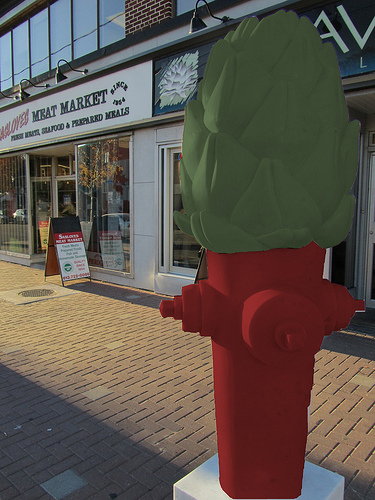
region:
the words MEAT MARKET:
[26, 91, 104, 126]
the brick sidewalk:
[51, 294, 210, 417]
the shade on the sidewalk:
[35, 419, 101, 475]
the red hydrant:
[166, 254, 354, 483]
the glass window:
[76, 151, 137, 268]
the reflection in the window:
[98, 225, 125, 270]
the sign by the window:
[40, 210, 89, 289]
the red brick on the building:
[124, 8, 162, 24]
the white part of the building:
[137, 188, 149, 227]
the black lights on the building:
[4, 54, 91, 106]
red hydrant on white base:
[174, 250, 357, 498]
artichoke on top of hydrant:
[173, 31, 365, 266]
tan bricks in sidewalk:
[59, 322, 146, 383]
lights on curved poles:
[16, 55, 91, 101]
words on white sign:
[62, 241, 87, 277]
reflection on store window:
[79, 138, 130, 245]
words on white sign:
[29, 75, 134, 139]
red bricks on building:
[124, 2, 172, 29]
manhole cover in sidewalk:
[17, 283, 65, 307]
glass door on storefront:
[48, 164, 82, 215]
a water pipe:
[209, 280, 295, 496]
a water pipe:
[235, 346, 289, 487]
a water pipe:
[230, 390, 255, 469]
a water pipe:
[217, 387, 246, 486]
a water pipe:
[220, 292, 265, 490]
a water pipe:
[214, 329, 240, 469]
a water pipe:
[241, 343, 253, 494]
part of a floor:
[133, 388, 177, 445]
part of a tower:
[240, 374, 283, 416]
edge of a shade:
[338, 349, 369, 373]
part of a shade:
[126, 432, 162, 468]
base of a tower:
[180, 476, 189, 485]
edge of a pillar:
[215, 425, 219, 457]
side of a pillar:
[251, 391, 283, 433]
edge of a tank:
[339, 302, 362, 370]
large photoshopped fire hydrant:
[151, 25, 373, 499]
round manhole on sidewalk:
[6, 279, 75, 309]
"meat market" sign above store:
[0, 73, 166, 127]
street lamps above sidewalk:
[5, 4, 232, 114]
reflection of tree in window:
[78, 139, 136, 240]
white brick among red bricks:
[34, 466, 96, 498]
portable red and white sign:
[35, 210, 94, 298]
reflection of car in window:
[5, 203, 31, 229]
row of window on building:
[6, 4, 141, 57]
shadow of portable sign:
[68, 267, 182, 313]